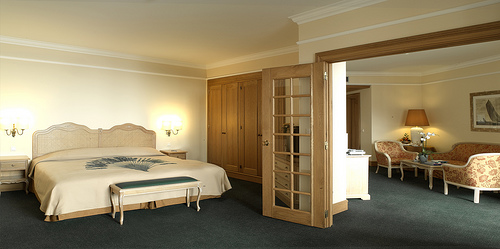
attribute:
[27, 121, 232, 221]
bed — king sized, large, made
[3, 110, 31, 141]
light — on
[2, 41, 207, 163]
wall — white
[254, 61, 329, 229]
door — open, brown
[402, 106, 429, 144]
lamp — on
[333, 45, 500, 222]
room — sitting area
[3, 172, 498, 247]
floor — carpet, gray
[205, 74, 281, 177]
closet doors — closed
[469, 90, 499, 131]
painting — large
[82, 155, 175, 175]
design — green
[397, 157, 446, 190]
table — woode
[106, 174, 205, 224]
bench — tan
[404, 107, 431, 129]
lampshade — gold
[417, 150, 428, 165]
vase — gray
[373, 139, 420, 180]
chair — orange, padded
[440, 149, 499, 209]
chair — orange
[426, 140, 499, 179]
couch — orange, padded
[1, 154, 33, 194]
nightstand — brown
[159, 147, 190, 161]
nightstand — brown